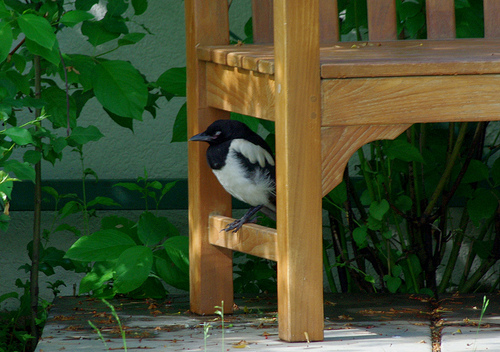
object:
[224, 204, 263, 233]
leg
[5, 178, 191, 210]
stripe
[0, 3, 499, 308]
green plants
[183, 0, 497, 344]
bench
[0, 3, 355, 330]
wall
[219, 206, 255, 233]
leg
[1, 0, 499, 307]
light green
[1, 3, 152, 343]
tree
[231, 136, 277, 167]
wing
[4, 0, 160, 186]
leaves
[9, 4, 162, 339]
plant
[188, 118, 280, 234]
bird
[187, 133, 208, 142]
beak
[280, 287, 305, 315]
edge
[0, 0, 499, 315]
building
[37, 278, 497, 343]
shadows